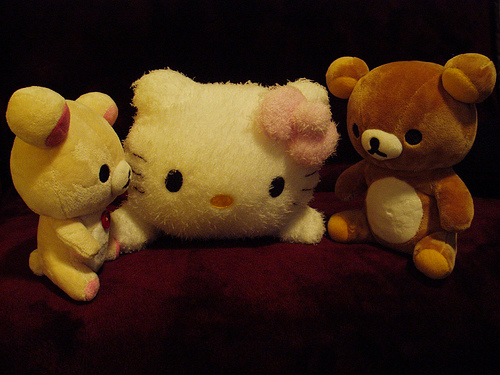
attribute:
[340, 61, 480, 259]
bear — brown, tan, here, casting, stuffed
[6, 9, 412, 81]
background — black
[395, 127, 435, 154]
eye — black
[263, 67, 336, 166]
bow tie — worn, pink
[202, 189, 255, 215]
nose — yellow, pink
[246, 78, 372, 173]
bow — pink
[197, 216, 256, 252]
mouth — invisible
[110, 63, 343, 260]
kitty — terrycloth, stuffed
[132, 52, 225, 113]
ears — pink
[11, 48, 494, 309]
animals — stuffed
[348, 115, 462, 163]
eyes — black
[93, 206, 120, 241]
button — red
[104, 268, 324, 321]
chair — red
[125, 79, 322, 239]
head — horizontally oval, almost round